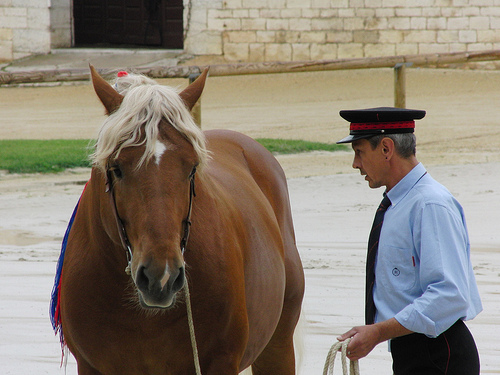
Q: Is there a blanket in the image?
A: Yes, there is a blanket.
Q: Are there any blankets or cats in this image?
A: Yes, there is a blanket.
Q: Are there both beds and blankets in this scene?
A: No, there is a blanket but no beds.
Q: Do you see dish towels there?
A: No, there are no dish towels.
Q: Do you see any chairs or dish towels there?
A: No, there are no dish towels or chairs.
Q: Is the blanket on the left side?
A: Yes, the blanket is on the left of the image.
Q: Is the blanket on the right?
A: No, the blanket is on the left of the image.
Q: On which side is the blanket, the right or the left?
A: The blanket is on the left of the image.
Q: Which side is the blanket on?
A: The blanket is on the left of the image.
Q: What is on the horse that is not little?
A: The blanket is on the horse.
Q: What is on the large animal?
A: The blanket is on the horse.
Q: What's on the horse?
A: The blanket is on the horse.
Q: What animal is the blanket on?
A: The blanket is on the horse.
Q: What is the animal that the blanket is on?
A: The animal is a horse.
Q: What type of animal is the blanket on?
A: The blanket is on the horse.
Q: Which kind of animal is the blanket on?
A: The blanket is on the horse.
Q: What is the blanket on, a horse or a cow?
A: The blanket is on a horse.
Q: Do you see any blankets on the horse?
A: Yes, there is a blanket on the horse.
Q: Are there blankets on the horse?
A: Yes, there is a blanket on the horse.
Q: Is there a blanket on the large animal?
A: Yes, there is a blanket on the horse.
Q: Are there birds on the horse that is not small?
A: No, there is a blanket on the horse.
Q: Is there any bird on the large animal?
A: No, there is a blanket on the horse.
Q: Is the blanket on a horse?
A: Yes, the blanket is on a horse.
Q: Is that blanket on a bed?
A: No, the blanket is on a horse.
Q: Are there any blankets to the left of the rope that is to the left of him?
A: Yes, there is a blanket to the left of the rope.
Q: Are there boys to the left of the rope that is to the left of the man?
A: No, there is a blanket to the left of the rope.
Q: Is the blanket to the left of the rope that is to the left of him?
A: Yes, the blanket is to the left of the rope.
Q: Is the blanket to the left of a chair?
A: No, the blanket is to the left of the rope.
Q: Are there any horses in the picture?
A: Yes, there is a horse.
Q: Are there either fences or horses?
A: Yes, there is a horse.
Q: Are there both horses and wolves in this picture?
A: No, there is a horse but no wolves.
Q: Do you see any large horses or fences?
A: Yes, there is a large horse.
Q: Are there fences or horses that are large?
A: Yes, the horse is large.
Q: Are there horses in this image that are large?
A: Yes, there is a large horse.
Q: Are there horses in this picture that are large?
A: Yes, there is a horse that is large.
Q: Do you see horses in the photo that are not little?
A: Yes, there is a large horse.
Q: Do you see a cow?
A: No, there are no cows.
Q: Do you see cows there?
A: No, there are no cows.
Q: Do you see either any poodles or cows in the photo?
A: No, there are no cows or poodles.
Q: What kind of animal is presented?
A: The animal is a horse.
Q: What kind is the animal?
A: The animal is a horse.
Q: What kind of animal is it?
A: The animal is a horse.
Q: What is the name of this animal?
A: This is a horse.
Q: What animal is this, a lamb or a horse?
A: This is a horse.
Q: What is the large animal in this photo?
A: The animal is a horse.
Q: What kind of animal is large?
A: The animal is a horse.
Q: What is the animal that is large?
A: The animal is a horse.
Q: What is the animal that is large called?
A: The animal is a horse.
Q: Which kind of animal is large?
A: The animal is a horse.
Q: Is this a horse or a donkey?
A: This is a horse.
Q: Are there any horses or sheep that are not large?
A: No, there is a horse but it is large.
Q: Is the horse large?
A: Yes, the horse is large.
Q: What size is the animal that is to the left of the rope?
A: The horse is large.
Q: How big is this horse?
A: The horse is large.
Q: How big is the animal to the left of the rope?
A: The horse is large.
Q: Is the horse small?
A: No, the horse is large.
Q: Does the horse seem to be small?
A: No, the horse is large.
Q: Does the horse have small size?
A: No, the horse is large.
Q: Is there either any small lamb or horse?
A: No, there is a horse but it is large.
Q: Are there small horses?
A: No, there is a horse but it is large.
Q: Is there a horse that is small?
A: No, there is a horse but it is large.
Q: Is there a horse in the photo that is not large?
A: No, there is a horse but it is large.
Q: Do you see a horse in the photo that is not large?
A: No, there is a horse but it is large.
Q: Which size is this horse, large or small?
A: The horse is large.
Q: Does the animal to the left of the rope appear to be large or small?
A: The horse is large.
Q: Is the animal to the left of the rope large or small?
A: The horse is large.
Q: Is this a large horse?
A: Yes, this is a large horse.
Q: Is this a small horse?
A: No, this is a large horse.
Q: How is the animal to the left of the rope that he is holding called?
A: The animal is a horse.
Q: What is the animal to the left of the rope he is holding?
A: The animal is a horse.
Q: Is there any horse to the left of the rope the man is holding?
A: Yes, there is a horse to the left of the rope.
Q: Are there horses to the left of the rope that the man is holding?
A: Yes, there is a horse to the left of the rope.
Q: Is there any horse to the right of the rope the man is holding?
A: No, the horse is to the left of the rope.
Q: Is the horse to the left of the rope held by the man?
A: Yes, the horse is to the left of the rope.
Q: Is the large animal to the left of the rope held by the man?
A: Yes, the horse is to the left of the rope.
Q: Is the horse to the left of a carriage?
A: No, the horse is to the left of the rope.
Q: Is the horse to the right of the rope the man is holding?
A: No, the horse is to the left of the rope.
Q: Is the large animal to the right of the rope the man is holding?
A: No, the horse is to the left of the rope.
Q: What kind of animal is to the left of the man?
A: The animal is a horse.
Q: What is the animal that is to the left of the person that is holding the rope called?
A: The animal is a horse.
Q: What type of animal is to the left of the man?
A: The animal is a horse.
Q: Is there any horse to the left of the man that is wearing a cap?
A: Yes, there is a horse to the left of the man.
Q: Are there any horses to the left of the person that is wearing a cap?
A: Yes, there is a horse to the left of the man.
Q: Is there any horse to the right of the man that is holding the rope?
A: No, the horse is to the left of the man.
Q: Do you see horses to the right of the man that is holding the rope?
A: No, the horse is to the left of the man.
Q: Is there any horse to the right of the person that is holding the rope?
A: No, the horse is to the left of the man.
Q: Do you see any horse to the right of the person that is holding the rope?
A: No, the horse is to the left of the man.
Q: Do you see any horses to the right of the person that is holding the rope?
A: No, the horse is to the left of the man.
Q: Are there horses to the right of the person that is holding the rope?
A: No, the horse is to the left of the man.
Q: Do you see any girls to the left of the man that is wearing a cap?
A: No, there is a horse to the left of the man.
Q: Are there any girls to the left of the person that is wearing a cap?
A: No, there is a horse to the left of the man.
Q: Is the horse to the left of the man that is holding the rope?
A: Yes, the horse is to the left of the man.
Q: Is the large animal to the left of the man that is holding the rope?
A: Yes, the horse is to the left of the man.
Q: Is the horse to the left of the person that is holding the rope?
A: Yes, the horse is to the left of the man.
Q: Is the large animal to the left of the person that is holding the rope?
A: Yes, the horse is to the left of the man.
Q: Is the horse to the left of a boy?
A: No, the horse is to the left of the man.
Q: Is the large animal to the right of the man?
A: No, the horse is to the left of the man.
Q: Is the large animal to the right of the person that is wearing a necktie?
A: No, the horse is to the left of the man.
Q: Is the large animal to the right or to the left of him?
A: The horse is to the left of the man.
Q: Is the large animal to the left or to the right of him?
A: The horse is to the left of the man.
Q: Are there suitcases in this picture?
A: No, there are no suitcases.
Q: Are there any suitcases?
A: No, there are no suitcases.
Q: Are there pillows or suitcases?
A: No, there are no suitcases or pillows.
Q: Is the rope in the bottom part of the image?
A: Yes, the rope is in the bottom of the image.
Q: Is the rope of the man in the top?
A: No, the rope is in the bottom of the image.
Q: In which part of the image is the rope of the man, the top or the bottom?
A: The rope is in the bottom of the image.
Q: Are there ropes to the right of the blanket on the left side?
A: Yes, there is a rope to the right of the blanket.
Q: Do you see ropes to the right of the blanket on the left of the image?
A: Yes, there is a rope to the right of the blanket.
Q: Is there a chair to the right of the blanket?
A: No, there is a rope to the right of the blanket.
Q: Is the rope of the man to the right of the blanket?
A: Yes, the rope is to the right of the blanket.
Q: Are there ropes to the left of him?
A: Yes, there is a rope to the left of the man.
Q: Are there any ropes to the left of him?
A: Yes, there is a rope to the left of the man.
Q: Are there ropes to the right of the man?
A: No, the rope is to the left of the man.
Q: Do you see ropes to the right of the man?
A: No, the rope is to the left of the man.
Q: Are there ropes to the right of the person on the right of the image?
A: No, the rope is to the left of the man.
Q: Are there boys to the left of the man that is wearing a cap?
A: No, there is a rope to the left of the man.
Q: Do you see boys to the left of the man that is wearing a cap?
A: No, there is a rope to the left of the man.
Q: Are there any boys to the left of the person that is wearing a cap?
A: No, there is a rope to the left of the man.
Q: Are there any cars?
A: No, there are no cars.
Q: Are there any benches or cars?
A: No, there are no cars or benches.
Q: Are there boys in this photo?
A: No, there are no boys.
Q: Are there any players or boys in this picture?
A: No, there are no boys or players.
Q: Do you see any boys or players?
A: No, there are no boys or players.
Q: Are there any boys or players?
A: No, there are no boys or players.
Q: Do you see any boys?
A: No, there are no boys.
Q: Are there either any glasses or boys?
A: No, there are no boys or glasses.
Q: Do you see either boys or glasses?
A: No, there are no boys or glasses.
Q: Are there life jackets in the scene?
A: No, there are no life jackets.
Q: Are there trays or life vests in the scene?
A: No, there are no life vests or trays.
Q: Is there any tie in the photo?
A: Yes, there is a tie.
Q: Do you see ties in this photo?
A: Yes, there is a tie.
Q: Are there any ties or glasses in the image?
A: Yes, there is a tie.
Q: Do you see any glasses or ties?
A: Yes, there is a tie.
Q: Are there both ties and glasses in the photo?
A: No, there is a tie but no glasses.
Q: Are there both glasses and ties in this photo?
A: No, there is a tie but no glasses.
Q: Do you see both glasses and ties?
A: No, there is a tie but no glasses.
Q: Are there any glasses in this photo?
A: No, there are no glasses.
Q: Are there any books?
A: No, there are no books.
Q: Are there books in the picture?
A: No, there are no books.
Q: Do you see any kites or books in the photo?
A: No, there are no books or kites.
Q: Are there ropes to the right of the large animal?
A: Yes, there is a rope to the right of the horse.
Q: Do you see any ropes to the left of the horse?
A: No, the rope is to the right of the horse.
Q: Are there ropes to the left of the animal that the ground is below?
A: No, the rope is to the right of the horse.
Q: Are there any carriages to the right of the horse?
A: No, there is a rope to the right of the horse.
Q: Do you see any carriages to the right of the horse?
A: No, there is a rope to the right of the horse.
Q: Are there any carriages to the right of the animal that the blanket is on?
A: No, there is a rope to the right of the horse.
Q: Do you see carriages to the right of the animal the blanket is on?
A: No, there is a rope to the right of the horse.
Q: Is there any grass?
A: Yes, there is grass.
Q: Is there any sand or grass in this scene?
A: Yes, there is grass.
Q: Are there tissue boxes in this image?
A: No, there are no tissue boxes.